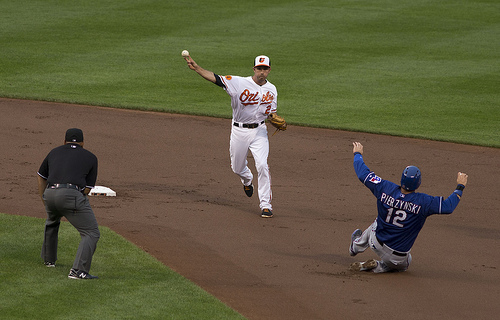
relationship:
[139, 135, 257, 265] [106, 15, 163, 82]
dirt on field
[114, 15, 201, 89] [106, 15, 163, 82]
grass on field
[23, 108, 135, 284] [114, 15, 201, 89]
man on grass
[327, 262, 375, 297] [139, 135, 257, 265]
footprint in dirt